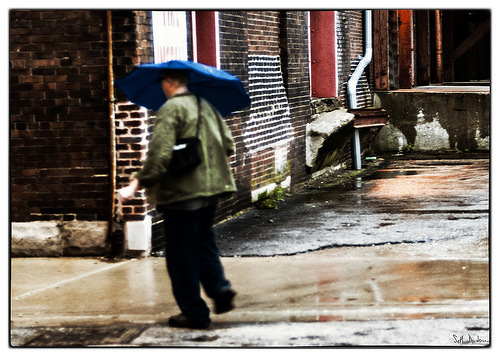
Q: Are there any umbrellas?
A: Yes, there is an umbrella.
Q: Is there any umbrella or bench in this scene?
A: Yes, there is an umbrella.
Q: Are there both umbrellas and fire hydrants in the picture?
A: No, there is an umbrella but no fire hydrants.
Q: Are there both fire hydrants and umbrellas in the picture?
A: No, there is an umbrella but no fire hydrants.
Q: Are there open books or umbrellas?
A: Yes, there is an open umbrella.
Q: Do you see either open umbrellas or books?
A: Yes, there is an open umbrella.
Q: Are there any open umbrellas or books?
A: Yes, there is an open umbrella.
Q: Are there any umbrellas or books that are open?
A: Yes, the umbrella is open.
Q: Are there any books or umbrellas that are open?
A: Yes, the umbrella is open.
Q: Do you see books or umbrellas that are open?
A: Yes, the umbrella is open.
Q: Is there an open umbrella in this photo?
A: Yes, there is an open umbrella.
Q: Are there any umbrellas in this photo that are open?
A: Yes, there is an umbrella that is open.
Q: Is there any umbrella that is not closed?
A: Yes, there is a open umbrella.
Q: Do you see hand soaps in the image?
A: No, there are no hand soaps.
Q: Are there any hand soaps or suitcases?
A: No, there are no hand soaps or suitcases.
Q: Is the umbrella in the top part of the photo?
A: Yes, the umbrella is in the top of the image.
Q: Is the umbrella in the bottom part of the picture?
A: No, the umbrella is in the top of the image.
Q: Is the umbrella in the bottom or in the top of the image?
A: The umbrella is in the top of the image.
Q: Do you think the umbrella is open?
A: Yes, the umbrella is open.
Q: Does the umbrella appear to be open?
A: Yes, the umbrella is open.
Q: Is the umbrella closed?
A: No, the umbrella is open.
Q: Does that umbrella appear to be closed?
A: No, the umbrella is open.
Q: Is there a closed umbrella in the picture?
A: No, there is an umbrella but it is open.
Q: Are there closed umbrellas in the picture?
A: No, there is an umbrella but it is open.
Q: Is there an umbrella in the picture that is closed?
A: No, there is an umbrella but it is open.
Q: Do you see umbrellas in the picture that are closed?
A: No, there is an umbrella but it is open.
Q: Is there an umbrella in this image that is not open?
A: No, there is an umbrella but it is open.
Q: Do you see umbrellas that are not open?
A: No, there is an umbrella but it is open.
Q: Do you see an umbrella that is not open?
A: No, there is an umbrella but it is open.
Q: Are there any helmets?
A: No, there are no helmets.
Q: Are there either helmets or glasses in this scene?
A: No, there are no helmets or glasses.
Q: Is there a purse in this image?
A: Yes, there is a purse.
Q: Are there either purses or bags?
A: Yes, there is a purse.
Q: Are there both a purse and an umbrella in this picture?
A: Yes, there are both a purse and an umbrella.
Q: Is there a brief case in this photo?
A: No, there are no briefcases.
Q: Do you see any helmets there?
A: No, there are no helmets.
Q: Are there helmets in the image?
A: No, there are no helmets.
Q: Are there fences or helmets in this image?
A: No, there are no helmets or fences.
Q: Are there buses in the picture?
A: No, there are no buses.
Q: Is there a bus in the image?
A: No, there are no buses.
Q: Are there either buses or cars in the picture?
A: No, there are no buses or cars.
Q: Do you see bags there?
A: Yes, there is a bag.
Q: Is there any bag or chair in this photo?
A: Yes, there is a bag.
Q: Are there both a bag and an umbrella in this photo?
A: Yes, there are both a bag and an umbrella.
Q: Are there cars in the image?
A: No, there are no cars.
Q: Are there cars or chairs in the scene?
A: No, there are no cars or chairs.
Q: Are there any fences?
A: No, there are no fences.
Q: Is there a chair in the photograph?
A: No, there are no chairs.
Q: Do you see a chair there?
A: No, there are no chairs.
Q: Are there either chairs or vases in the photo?
A: No, there are no chairs or vases.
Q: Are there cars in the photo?
A: No, there are no cars.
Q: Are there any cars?
A: No, there are no cars.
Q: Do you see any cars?
A: No, there are no cars.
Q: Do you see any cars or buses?
A: No, there are no cars or buses.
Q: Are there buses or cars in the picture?
A: No, there are no cars or buses.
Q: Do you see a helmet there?
A: No, there are no helmets.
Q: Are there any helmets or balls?
A: No, there are no helmets or balls.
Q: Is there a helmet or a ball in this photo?
A: No, there are no helmets or balls.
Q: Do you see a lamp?
A: No, there are no lamps.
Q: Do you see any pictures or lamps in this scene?
A: No, there are no lamps or pictures.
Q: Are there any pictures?
A: No, there are no pictures.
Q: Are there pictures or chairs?
A: No, there are no pictures or chairs.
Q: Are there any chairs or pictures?
A: No, there are no pictures or chairs.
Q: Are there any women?
A: Yes, there is a woman.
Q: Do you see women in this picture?
A: Yes, there is a woman.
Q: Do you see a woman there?
A: Yes, there is a woman.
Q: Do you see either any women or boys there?
A: Yes, there is a woman.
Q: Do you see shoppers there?
A: No, there are no shoppers.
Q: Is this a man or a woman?
A: This is a woman.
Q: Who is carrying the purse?
A: The woman is carrying the purse.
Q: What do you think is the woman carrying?
A: The woman is carrying a purse.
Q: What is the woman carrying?
A: The woman is carrying a purse.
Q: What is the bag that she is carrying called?
A: The bag is a purse.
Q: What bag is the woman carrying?
A: The woman is carrying a purse.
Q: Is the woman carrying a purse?
A: Yes, the woman is carrying a purse.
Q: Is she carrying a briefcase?
A: No, the woman is carrying a purse.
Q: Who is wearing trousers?
A: The woman is wearing trousers.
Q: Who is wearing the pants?
A: The woman is wearing trousers.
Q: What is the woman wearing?
A: The woman is wearing trousers.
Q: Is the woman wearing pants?
A: Yes, the woman is wearing pants.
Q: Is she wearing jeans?
A: No, the woman is wearing pants.